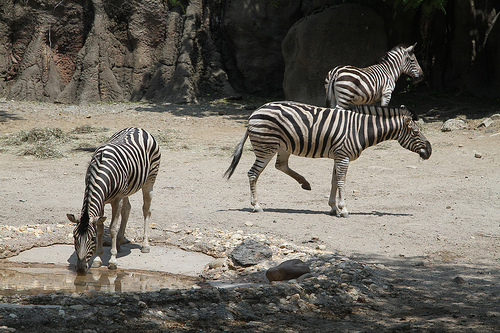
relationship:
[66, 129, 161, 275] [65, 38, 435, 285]
black white zebra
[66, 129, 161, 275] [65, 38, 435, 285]
black white zebras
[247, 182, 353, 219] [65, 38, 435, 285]
hooves of zebra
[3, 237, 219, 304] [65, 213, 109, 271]
pond zebra drinking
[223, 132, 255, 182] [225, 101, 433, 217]
tail of zebra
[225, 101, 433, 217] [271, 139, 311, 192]
zebra left leg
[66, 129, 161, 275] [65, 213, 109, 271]
zebra drinking water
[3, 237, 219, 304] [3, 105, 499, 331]
paddle water pen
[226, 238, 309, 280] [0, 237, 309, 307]
stones next water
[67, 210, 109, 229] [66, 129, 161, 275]
ears of zebra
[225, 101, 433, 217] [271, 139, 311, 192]
zebra legs elevated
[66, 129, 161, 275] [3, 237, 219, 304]
zebra drinks hole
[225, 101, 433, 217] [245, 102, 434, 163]
zebra stripes side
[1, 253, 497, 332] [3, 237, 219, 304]
tree shade hole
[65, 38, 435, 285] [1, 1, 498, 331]
zebras in habitat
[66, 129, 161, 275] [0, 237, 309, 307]
zebra drinking water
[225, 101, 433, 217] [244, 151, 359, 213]
zebra standing legs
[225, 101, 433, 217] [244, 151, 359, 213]
zebra three legs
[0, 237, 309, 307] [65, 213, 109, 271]
water hole drink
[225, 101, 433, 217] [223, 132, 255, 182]
zebras black tail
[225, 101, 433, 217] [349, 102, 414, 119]
zebras black mane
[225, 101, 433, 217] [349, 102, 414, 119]
zebras white mane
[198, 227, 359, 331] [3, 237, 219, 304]
rocks near hole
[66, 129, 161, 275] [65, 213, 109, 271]
zebra head drink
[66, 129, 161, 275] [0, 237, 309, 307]
zebra head water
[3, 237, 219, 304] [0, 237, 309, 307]
puddle provides water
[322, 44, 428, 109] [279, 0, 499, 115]
moving cooler area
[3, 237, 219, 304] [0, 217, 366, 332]
wateing hole rim